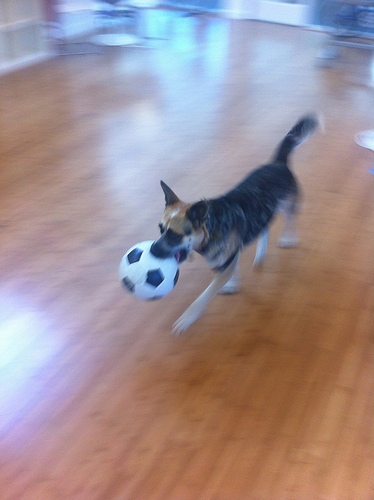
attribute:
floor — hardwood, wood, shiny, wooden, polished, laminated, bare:
[30, 52, 358, 415]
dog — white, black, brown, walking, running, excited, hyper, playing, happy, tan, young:
[163, 117, 324, 312]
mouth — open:
[148, 241, 197, 268]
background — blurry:
[4, 4, 372, 93]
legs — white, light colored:
[251, 218, 313, 266]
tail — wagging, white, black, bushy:
[275, 108, 324, 161]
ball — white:
[122, 248, 186, 305]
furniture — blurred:
[278, 2, 373, 39]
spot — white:
[168, 206, 182, 221]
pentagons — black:
[127, 248, 165, 289]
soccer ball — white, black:
[118, 242, 184, 303]